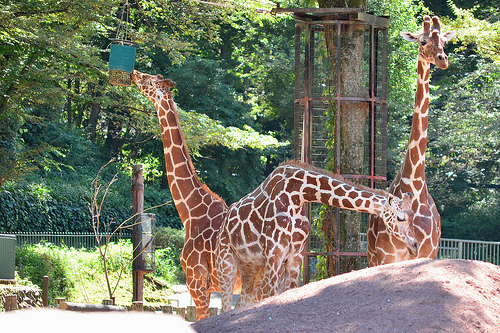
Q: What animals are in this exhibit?
A: Giraffes.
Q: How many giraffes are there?
A: Three.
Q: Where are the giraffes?
A: The zoo.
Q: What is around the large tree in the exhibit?
A: A cage.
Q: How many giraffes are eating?
A: One.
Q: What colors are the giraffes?
A: Brown and cream.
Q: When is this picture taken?
A: During the day.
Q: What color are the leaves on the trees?
A: Green.